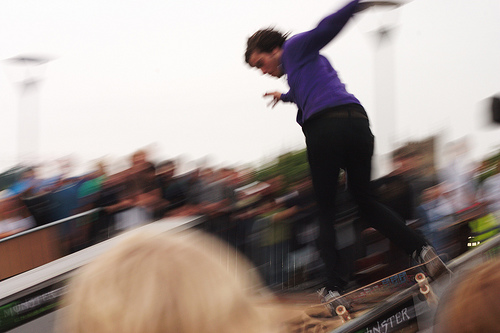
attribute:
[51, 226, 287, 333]
person — blonde, hair, head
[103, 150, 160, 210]
person — blurry, spectator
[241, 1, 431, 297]
skateboarder — fast, performing, guy, man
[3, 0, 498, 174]
sky — clear, bright, gray, white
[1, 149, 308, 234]
background — blurry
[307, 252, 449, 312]
skateboard — black, blue, blurry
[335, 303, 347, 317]
wheel — red, white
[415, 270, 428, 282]
wheel — white, red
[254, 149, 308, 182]
trees — green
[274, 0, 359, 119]
shirt — purple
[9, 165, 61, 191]
person — blurry, spectator, onlooker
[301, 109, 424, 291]
jeans — black, pants, skinny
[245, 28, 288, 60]
hair — brown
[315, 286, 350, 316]
sneaker — white, black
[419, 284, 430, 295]
wheel — red, white